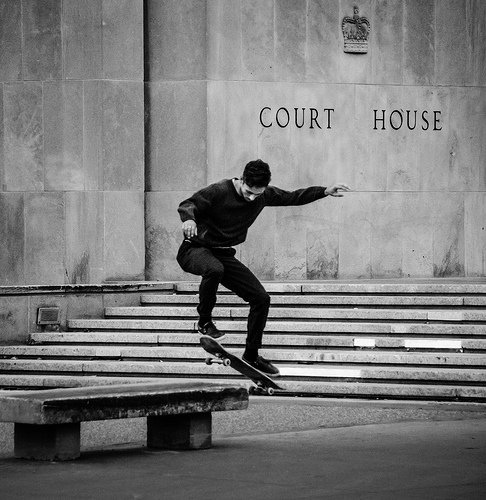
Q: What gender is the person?
A: Male.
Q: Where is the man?
A: Air.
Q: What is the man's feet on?
A: Skateboard.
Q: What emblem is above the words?
A: Crown.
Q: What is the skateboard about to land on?
A: Bench.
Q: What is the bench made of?
A: Concrete.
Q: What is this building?
A: Court House.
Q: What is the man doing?
A: Skateboarding.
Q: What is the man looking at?
A: The board.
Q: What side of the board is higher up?
A: The left side.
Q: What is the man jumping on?
A: Bench.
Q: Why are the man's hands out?
A: For balance.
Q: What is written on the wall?
A: Court House.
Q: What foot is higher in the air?
A: The man's right foot.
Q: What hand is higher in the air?
A: The left.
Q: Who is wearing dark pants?
A: The skater.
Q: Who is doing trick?
A: A man.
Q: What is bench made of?
A: Concrete.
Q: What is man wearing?
A: Shoes.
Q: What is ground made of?
A: Concrete.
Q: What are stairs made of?
A: Concrete.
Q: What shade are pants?
A: Dark.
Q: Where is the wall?
A: Behind man.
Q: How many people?
A: 1.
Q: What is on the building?
A: Writing.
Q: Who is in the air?
A: The skater.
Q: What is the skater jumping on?
A: Bench.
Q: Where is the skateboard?
A: Under the skater.